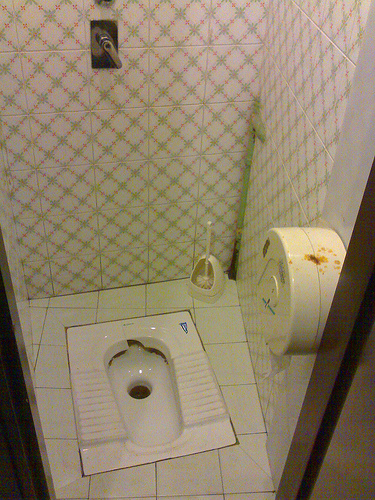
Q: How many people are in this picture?
A: Zero.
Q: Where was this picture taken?
A: Bathroom.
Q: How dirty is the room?
A: Very dirty.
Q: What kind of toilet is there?
A: Squat toilet.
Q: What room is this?
A: Bathroom.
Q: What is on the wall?
A: Tiles.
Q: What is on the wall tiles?
A: Designs.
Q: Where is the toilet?
A: On the floor.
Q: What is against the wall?
A: The cane.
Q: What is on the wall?
A: A pattern.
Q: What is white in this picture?
A: The toilet.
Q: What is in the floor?
A: The toilet.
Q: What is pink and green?
A: The wallpaper.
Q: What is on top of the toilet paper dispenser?
A: Some brown dirt.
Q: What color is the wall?
A: The walls are green,red,white.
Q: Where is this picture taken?
A: In a bathroom.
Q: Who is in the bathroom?
A: Nobody is in the bathroom.